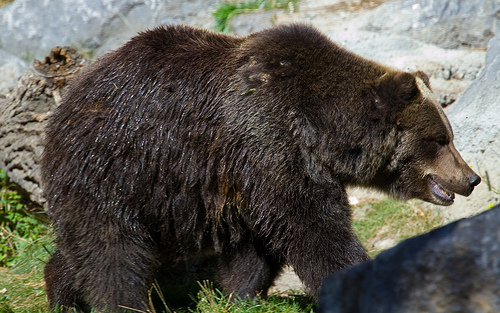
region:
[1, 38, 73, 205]
rough barked log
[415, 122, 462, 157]
eye squinting from the sun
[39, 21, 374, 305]
thick drak brown fur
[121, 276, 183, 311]
long gradd grows up rear leg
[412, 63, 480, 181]
lighter fur covers center of face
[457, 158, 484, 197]
black squared nose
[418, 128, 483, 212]
this bear is panting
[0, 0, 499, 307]
a rocky grey terraine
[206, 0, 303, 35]
grass grows between rocks behind bear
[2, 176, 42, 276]
weeds grow near log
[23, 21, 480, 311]
large black bear walking in the grass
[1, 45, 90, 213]
bark on a tree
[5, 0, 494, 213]
group of large rocks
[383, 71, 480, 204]
bears mouth is open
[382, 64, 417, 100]
small round ear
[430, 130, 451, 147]
black eye surrounded by fur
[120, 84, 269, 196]
sun light shining on the bears fur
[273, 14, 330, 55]
tuft of hair on bears shoulder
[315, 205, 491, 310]
a rock in the shade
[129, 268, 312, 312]
grass underneath the bear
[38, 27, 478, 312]
A brown hairy bear.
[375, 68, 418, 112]
One of the bear's ears.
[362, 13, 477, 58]
Part of the rocks.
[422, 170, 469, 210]
The bear's open mouth.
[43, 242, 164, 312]
The back feet of the bear.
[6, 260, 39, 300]
Part of the green grass.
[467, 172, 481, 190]
The bear's black nose.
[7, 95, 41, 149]
Part of a piece of wood.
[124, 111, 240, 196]
The bear's brown fur.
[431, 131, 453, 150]
The eye of the bear.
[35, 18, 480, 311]
this grizzly bear appears to be in a zoo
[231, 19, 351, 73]
this hump on the bear's back identifies it as a grizzley bear.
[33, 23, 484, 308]
the bear's coat is brown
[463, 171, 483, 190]
the bear's nose is black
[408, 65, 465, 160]
this bear appears to have a lighter colored patch of fur on the top of its head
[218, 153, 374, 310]
the bear's front legs are very large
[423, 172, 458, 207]
some of the bear's teeth are visible.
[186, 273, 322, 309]
grass is growing on the ground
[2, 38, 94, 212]
this looks like an old stump.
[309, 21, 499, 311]
rocks in the foreground and background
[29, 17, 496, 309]
a black bear walking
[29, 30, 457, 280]
a black bear walking outside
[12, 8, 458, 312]
a black bear walking in a grassy area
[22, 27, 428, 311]
a black bear walking in a rocky area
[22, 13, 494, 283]
a large bear walking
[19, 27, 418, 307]
a large bear walking outside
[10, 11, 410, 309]
a large bear walking in a grassy area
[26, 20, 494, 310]
a large bear walking in a rocky area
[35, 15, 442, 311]
a large black bear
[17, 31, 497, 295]
a large black bear walking outside